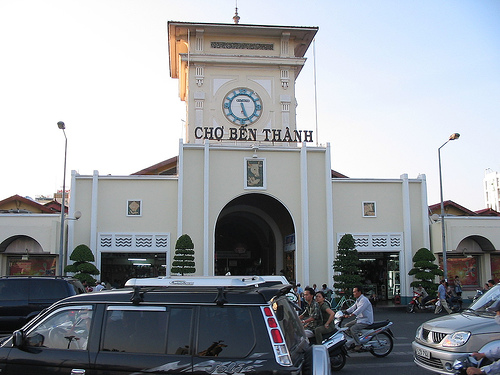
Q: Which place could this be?
A: It is a market.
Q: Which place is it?
A: It is a market.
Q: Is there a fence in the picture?
A: No, there are no fences.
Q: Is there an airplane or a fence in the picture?
A: No, there are no fences or airplanes.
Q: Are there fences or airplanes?
A: No, there are no fences or airplanes.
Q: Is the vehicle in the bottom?
A: Yes, the vehicle is in the bottom of the image.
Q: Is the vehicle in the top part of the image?
A: No, the vehicle is in the bottom of the image.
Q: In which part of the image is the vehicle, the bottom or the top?
A: The vehicle is in the bottom of the image.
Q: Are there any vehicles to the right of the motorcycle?
A: Yes, there is a vehicle to the right of the motorcycle.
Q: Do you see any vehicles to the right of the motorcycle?
A: Yes, there is a vehicle to the right of the motorcycle.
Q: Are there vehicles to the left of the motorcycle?
A: No, the vehicle is to the right of the motorcycle.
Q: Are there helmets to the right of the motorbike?
A: No, there is a vehicle to the right of the motorbike.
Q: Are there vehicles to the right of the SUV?
A: Yes, there is a vehicle to the right of the SUV.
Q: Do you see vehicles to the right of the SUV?
A: Yes, there is a vehicle to the right of the SUV.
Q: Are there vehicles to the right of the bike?
A: Yes, there is a vehicle to the right of the bike.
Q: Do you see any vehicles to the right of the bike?
A: Yes, there is a vehicle to the right of the bike.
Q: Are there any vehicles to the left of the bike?
A: No, the vehicle is to the right of the bike.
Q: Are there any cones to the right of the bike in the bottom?
A: No, there is a vehicle to the right of the bike.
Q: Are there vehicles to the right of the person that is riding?
A: Yes, there is a vehicle to the right of the person.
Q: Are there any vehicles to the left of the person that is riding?
A: No, the vehicle is to the right of the person.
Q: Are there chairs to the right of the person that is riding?
A: No, there is a vehicle to the right of the person.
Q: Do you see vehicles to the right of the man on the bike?
A: Yes, there is a vehicle to the right of the man.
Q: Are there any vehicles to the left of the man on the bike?
A: No, the vehicle is to the right of the man.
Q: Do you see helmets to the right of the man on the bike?
A: No, there is a vehicle to the right of the man.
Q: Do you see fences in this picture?
A: No, there are no fences.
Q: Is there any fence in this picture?
A: No, there are no fences.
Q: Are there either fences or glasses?
A: No, there are no fences or glasses.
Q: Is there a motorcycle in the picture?
A: Yes, there is a motorcycle.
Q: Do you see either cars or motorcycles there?
A: Yes, there is a motorcycle.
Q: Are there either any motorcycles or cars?
A: Yes, there is a motorcycle.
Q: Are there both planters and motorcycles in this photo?
A: No, there is a motorcycle but no planters.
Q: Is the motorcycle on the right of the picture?
A: Yes, the motorcycle is on the right of the image.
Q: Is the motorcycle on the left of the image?
A: No, the motorcycle is on the right of the image.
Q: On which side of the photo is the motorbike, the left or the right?
A: The motorbike is on the right of the image.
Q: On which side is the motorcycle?
A: The motorcycle is on the right of the image.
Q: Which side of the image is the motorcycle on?
A: The motorcycle is on the right of the image.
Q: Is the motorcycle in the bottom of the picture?
A: Yes, the motorcycle is in the bottom of the image.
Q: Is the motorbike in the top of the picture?
A: No, the motorbike is in the bottom of the image.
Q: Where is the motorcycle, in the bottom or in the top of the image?
A: The motorcycle is in the bottom of the image.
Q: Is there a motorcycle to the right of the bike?
A: Yes, there is a motorcycle to the right of the bike.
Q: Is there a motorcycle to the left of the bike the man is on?
A: No, the motorcycle is to the right of the bike.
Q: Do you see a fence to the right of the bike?
A: No, there is a motorcycle to the right of the bike.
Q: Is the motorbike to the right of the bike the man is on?
A: Yes, the motorbike is to the right of the bike.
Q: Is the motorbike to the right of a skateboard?
A: No, the motorbike is to the right of the bike.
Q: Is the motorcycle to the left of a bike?
A: No, the motorcycle is to the right of a bike.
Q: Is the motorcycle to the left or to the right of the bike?
A: The motorcycle is to the right of the bike.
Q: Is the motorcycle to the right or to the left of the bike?
A: The motorcycle is to the right of the bike.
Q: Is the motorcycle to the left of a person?
A: No, the motorcycle is to the right of a person.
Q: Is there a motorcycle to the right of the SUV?
A: Yes, there is a motorcycle to the right of the SUV.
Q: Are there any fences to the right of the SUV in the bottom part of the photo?
A: No, there is a motorcycle to the right of the SUV.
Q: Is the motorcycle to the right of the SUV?
A: Yes, the motorcycle is to the right of the SUV.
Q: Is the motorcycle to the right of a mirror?
A: No, the motorcycle is to the right of the SUV.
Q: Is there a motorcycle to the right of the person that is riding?
A: Yes, there is a motorcycle to the right of the person.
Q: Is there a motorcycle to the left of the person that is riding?
A: No, the motorcycle is to the right of the person.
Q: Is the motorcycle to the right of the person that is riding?
A: Yes, the motorcycle is to the right of the person.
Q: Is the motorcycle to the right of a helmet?
A: No, the motorcycle is to the right of the person.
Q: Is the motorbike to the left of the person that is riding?
A: No, the motorbike is to the right of the person.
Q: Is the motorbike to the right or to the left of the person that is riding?
A: The motorbike is to the right of the person.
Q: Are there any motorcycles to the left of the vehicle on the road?
A: Yes, there is a motorcycle to the left of the vehicle.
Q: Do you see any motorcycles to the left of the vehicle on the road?
A: Yes, there is a motorcycle to the left of the vehicle.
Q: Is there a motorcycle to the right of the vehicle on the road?
A: No, the motorcycle is to the left of the vehicle.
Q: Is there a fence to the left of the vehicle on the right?
A: No, there is a motorcycle to the left of the vehicle.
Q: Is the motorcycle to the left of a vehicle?
A: Yes, the motorcycle is to the left of a vehicle.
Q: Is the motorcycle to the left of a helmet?
A: No, the motorcycle is to the left of a vehicle.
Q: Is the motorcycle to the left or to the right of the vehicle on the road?
A: The motorcycle is to the left of the vehicle.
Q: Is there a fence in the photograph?
A: No, there are no fences.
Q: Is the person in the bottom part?
A: Yes, the person is in the bottom of the image.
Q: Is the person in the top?
A: No, the person is in the bottom of the image.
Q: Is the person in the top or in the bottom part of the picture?
A: The person is in the bottom of the image.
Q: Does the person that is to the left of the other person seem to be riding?
A: Yes, the person is riding.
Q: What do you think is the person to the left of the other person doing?
A: The person is riding.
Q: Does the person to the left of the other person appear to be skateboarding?
A: No, the person is riding.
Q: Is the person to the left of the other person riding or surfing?
A: The person is riding.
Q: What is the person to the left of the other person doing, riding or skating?
A: The person is riding.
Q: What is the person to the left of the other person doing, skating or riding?
A: The person is riding.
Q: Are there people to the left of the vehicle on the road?
A: Yes, there is a person to the left of the vehicle.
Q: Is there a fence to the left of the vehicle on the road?
A: No, there is a person to the left of the vehicle.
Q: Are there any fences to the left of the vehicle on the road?
A: No, there is a person to the left of the vehicle.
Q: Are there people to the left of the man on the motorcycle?
A: Yes, there is a person to the left of the man.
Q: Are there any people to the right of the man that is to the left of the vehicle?
A: No, the person is to the left of the man.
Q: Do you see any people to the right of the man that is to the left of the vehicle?
A: No, the person is to the left of the man.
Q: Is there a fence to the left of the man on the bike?
A: No, there is a person to the left of the man.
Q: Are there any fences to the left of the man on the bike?
A: No, there is a person to the left of the man.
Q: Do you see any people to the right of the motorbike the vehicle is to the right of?
A: No, the person is to the left of the motorbike.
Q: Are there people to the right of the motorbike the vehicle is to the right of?
A: No, the person is to the left of the motorbike.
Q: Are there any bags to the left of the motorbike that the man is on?
A: No, there is a person to the left of the motorcycle.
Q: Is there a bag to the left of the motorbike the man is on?
A: No, there is a person to the left of the motorcycle.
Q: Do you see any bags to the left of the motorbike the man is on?
A: No, there is a person to the left of the motorcycle.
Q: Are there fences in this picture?
A: No, there are no fences.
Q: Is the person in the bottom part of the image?
A: Yes, the person is in the bottom of the image.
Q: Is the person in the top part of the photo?
A: No, the person is in the bottom of the image.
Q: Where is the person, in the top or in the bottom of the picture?
A: The person is in the bottom of the image.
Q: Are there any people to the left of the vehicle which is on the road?
A: Yes, there is a person to the left of the vehicle.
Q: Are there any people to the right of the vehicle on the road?
A: No, the person is to the left of the vehicle.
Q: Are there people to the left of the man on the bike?
A: Yes, there is a person to the left of the man.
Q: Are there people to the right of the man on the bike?
A: No, the person is to the left of the man.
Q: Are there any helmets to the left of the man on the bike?
A: No, there is a person to the left of the man.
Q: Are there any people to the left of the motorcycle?
A: Yes, there is a person to the left of the motorcycle.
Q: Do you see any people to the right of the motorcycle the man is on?
A: No, the person is to the left of the motorbike.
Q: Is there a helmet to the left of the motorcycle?
A: No, there is a person to the left of the motorcycle.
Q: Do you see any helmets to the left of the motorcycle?
A: No, there is a person to the left of the motorcycle.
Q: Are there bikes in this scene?
A: Yes, there is a bike.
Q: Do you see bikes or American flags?
A: Yes, there is a bike.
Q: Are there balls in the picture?
A: No, there are no balls.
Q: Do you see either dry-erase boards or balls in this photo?
A: No, there are no balls or dry-erase boards.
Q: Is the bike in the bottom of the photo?
A: Yes, the bike is in the bottom of the image.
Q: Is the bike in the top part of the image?
A: No, the bike is in the bottom of the image.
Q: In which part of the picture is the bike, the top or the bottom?
A: The bike is in the bottom of the image.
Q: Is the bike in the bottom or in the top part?
A: The bike is in the bottom of the image.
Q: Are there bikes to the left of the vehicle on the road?
A: Yes, there is a bike to the left of the vehicle.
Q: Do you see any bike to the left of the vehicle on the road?
A: Yes, there is a bike to the left of the vehicle.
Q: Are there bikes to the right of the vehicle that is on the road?
A: No, the bike is to the left of the vehicle.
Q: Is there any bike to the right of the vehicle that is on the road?
A: No, the bike is to the left of the vehicle.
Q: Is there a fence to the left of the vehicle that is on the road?
A: No, there is a bike to the left of the vehicle.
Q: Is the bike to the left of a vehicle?
A: Yes, the bike is to the left of a vehicle.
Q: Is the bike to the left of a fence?
A: No, the bike is to the left of a vehicle.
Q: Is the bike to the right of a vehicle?
A: No, the bike is to the left of a vehicle.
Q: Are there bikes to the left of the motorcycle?
A: Yes, there is a bike to the left of the motorcycle.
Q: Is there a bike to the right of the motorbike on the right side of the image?
A: No, the bike is to the left of the motorcycle.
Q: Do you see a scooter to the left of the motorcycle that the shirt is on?
A: No, there is a bike to the left of the motorbike.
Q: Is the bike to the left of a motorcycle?
A: Yes, the bike is to the left of a motorcycle.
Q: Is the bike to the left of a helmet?
A: No, the bike is to the left of a motorcycle.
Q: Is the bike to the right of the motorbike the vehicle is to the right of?
A: No, the bike is to the left of the motorbike.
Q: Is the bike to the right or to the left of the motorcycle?
A: The bike is to the left of the motorcycle.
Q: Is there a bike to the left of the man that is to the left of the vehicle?
A: Yes, there is a bike to the left of the man.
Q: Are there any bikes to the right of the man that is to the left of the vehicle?
A: No, the bike is to the left of the man.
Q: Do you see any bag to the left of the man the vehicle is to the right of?
A: No, there is a bike to the left of the man.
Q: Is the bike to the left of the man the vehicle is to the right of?
A: Yes, the bike is to the left of the man.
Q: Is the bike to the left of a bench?
A: No, the bike is to the left of the man.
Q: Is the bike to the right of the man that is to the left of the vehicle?
A: No, the bike is to the left of the man.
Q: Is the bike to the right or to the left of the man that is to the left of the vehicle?
A: The bike is to the left of the man.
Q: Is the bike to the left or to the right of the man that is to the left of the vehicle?
A: The bike is to the left of the man.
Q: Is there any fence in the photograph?
A: No, there are no fences.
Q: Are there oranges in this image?
A: No, there are no oranges.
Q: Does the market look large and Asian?
A: Yes, the market is large and asian.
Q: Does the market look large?
A: Yes, the market is large.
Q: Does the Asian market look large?
A: Yes, the market is large.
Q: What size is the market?
A: The market is large.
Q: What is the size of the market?
A: The market is large.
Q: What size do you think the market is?
A: The market is large.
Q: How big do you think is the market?
A: The market is large.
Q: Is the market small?
A: No, the market is large.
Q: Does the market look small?
A: No, the market is large.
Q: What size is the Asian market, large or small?
A: The market is large.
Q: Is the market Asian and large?
A: Yes, the market is Asian and large.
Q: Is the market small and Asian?
A: No, the market is Asian but large.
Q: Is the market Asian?
A: Yes, the market is asian.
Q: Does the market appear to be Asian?
A: Yes, the market is asian.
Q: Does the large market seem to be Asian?
A: Yes, the market is asian.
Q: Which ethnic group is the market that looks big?
A: The market is asian.